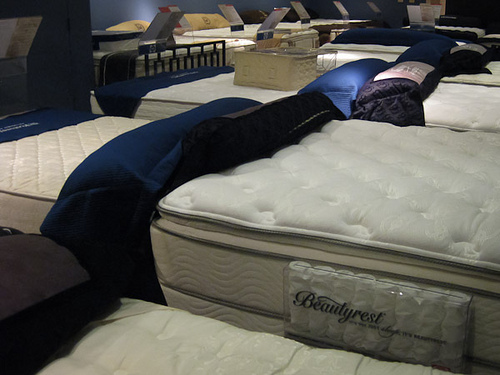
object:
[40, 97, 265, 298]
pillow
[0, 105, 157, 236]
mattress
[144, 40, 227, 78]
headboard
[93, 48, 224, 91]
of mattress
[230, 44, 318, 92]
basket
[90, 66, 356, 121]
mattress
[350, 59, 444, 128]
black pillow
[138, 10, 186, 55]
information sheets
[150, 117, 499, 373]
mattress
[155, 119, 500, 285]
pillow top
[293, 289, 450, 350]
brand name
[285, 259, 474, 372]
coil samples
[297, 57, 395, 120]
blue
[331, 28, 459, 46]
blue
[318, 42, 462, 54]
mattress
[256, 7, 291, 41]
information sheet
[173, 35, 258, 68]
mattress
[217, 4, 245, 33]
information sheet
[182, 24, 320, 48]
mattress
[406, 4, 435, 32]
information sheet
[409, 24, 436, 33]
holder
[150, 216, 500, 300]
piping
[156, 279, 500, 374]
box spring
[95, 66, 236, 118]
blue cover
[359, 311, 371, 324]
black letters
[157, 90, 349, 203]
pillow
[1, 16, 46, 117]
information sheet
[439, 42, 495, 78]
pillow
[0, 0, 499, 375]
store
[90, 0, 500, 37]
wall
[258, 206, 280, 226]
dip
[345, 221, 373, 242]
dip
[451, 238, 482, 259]
dip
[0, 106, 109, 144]
blankets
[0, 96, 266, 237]
bed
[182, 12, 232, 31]
pillow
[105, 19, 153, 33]
pillow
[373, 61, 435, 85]
printed fabric